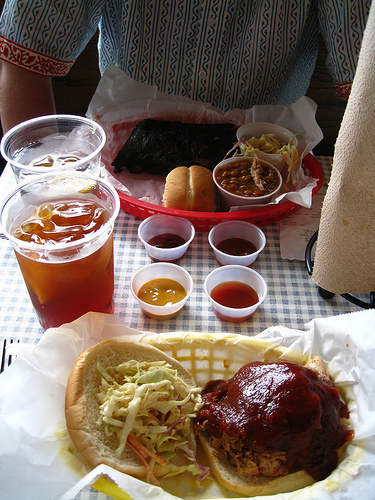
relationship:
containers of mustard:
[130, 262, 194, 321] [144, 282, 180, 302]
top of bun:
[181, 173, 209, 198] [161, 165, 221, 214]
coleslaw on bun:
[96, 361, 195, 469] [64, 337, 198, 482]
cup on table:
[1, 169, 122, 329] [4, 156, 374, 368]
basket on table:
[92, 102, 326, 231] [4, 156, 374, 368]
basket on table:
[56, 334, 365, 500] [4, 156, 374, 368]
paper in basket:
[96, 61, 323, 210] [92, 102, 326, 231]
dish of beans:
[212, 156, 283, 211] [229, 167, 247, 191]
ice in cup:
[34, 209, 94, 241] [1, 169, 122, 329]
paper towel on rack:
[313, 3, 373, 295] [304, 226, 375, 312]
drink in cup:
[10, 197, 115, 330] [1, 169, 122, 329]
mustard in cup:
[144, 282, 180, 302] [1, 169, 122, 329]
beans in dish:
[229, 167, 247, 191] [212, 156, 283, 211]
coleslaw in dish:
[244, 134, 299, 164] [235, 122, 299, 177]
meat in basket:
[112, 118, 239, 176] [92, 102, 326, 231]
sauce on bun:
[220, 366, 315, 430] [64, 337, 198, 482]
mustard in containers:
[144, 282, 180, 302] [130, 262, 194, 321]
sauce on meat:
[220, 366, 315, 430] [211, 431, 288, 480]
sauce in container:
[225, 287, 248, 303] [204, 265, 269, 324]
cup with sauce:
[209, 222, 268, 269] [227, 243, 252, 254]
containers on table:
[130, 214, 267, 322] [4, 156, 374, 368]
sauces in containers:
[155, 236, 246, 300] [130, 214, 267, 322]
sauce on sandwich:
[220, 366, 315, 430] [64, 337, 355, 496]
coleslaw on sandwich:
[96, 361, 195, 469] [64, 337, 355, 496]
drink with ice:
[21, 204, 109, 255] [34, 209, 94, 241]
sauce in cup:
[225, 287, 248, 303] [209, 222, 268, 269]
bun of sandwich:
[64, 337, 198, 482] [64, 337, 355, 496]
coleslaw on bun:
[96, 361, 195, 469] [161, 165, 221, 214]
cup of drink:
[1, 169, 122, 329] [10, 197, 115, 330]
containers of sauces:
[130, 214, 267, 322] [155, 236, 246, 300]